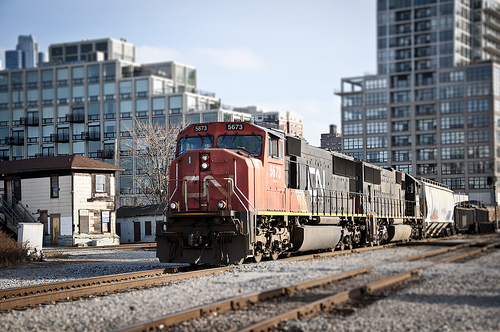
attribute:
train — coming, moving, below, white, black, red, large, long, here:
[173, 113, 299, 265]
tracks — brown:
[108, 254, 168, 312]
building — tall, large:
[358, 16, 482, 164]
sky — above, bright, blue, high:
[183, 10, 313, 67]